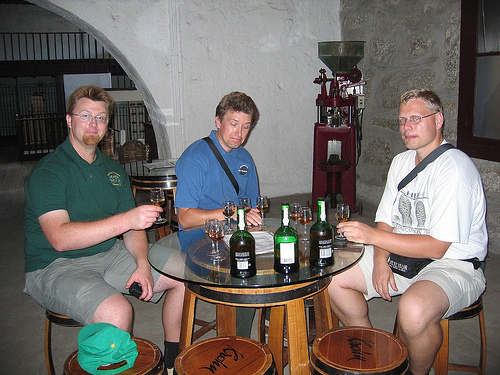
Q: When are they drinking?
A: Now.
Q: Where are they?
A: In a bar.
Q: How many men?
A: 3.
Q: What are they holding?
A: A glass.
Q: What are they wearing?
A: Shorts.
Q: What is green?
A: The bottles.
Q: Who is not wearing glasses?
A: The second man.